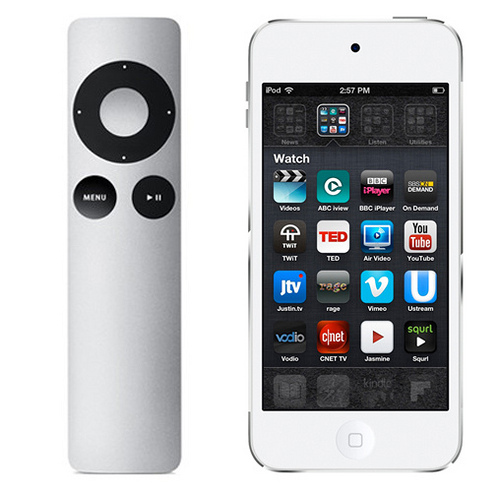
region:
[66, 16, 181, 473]
a silver and black Apple remote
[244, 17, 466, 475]
a white Apple iPhone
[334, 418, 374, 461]
an iPhone home button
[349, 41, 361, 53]
an iPhone video camera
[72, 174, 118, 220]
an Apple remote MENU button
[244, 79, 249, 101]
iPhone volume up button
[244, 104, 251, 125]
iPhone volume down button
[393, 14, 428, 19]
iPhone sleep button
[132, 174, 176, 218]
Apple remote pause/play button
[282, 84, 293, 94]
cellular strength meter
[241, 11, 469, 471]
the front view of a white iphone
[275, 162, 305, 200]
the app for watching videos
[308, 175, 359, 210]
the app for playing songs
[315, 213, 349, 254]
the app for watching TED videos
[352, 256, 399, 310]
the app for watching vimeo videos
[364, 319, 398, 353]
the app for watching youtube videos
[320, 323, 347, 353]
the app for watching object videos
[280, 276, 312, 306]
the app for watching jtv videos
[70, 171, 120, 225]
the menu button of a remote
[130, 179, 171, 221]
the play button of a remote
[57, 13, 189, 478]
the remote is made of metal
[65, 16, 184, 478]
the remote is grey in color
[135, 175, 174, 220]
the button is made of plastic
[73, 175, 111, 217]
the button is made of plastic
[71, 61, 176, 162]
the button is made of plastic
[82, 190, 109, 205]
lettering is on the button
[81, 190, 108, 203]
the lettering is white in color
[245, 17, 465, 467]
an iphone is on display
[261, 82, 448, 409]
the screen is made of glass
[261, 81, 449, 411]
an iPhone home screen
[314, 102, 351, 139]
an iPhone folder icon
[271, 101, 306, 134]
an iPhone folder icon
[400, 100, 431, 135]
an iPhone folder icon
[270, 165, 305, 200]
iPhone Videos app icon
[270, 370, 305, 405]
iPhone iBooks app icon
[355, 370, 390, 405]
iPhone Kindle app icon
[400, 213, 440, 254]
iPhone YouTube app icon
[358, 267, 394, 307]
iPhone Vimeo app icon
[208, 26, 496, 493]
white ipod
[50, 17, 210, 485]
remote control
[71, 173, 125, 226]
black menu button on the remote control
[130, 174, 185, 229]
play pause button on the remote control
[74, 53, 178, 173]
directional button on the remote control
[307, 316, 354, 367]
cnet button on the ipod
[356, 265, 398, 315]
vimeo button on the ipod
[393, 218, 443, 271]
youtube button on the ipod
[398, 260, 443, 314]
u stream button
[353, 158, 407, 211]
bbc player button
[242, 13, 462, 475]
A white iPhone with turned on display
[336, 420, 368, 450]
A white home button on an iphone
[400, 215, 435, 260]
YouTube app icon on display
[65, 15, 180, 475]
A white controller with three black buttons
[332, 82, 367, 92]
Time displayed on top of iphone screen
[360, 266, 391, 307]
Vimeo app icon on display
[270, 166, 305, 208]
video app icon on display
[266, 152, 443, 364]
a display of several apps on screen of iPhone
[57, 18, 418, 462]
these are apple products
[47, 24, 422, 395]
these are electronics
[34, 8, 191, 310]
this is a remote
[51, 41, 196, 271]
the remote is silver